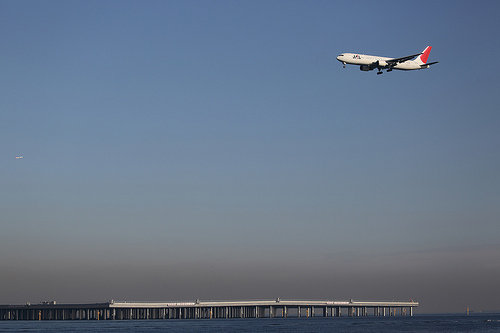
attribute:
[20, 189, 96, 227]
clouds — white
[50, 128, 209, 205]
sky — blue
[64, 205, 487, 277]
clouds — white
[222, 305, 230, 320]
wood post — grey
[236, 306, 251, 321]
wood post — grey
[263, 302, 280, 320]
wood post — grey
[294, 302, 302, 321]
wood post — grey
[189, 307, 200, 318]
wood post — grey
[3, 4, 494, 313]
sky — blue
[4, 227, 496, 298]
clouds — white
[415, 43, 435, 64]
tail — red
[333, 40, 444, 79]
plane — white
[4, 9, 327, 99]
sky — clear, blue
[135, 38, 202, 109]
clouds — white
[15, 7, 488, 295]
sky — blue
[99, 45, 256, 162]
sky — blue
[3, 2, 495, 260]
sky — blue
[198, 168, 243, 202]
clouds — white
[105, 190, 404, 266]
clouds — white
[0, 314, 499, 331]
ocean — calm, blue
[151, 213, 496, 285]
clouds — white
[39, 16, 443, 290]
sky — blue